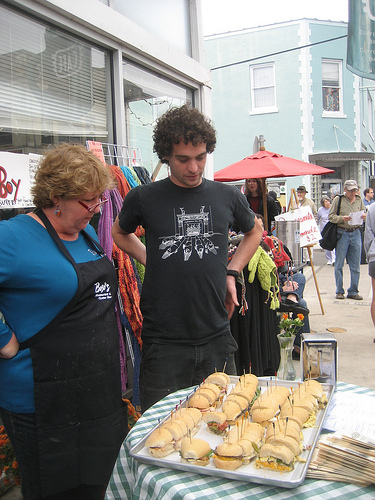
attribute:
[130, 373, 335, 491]
pan — silver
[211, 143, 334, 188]
umbrella — large, red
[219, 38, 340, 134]
building — two-story, blue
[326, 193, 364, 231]
shirt — green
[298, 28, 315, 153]
trim — white